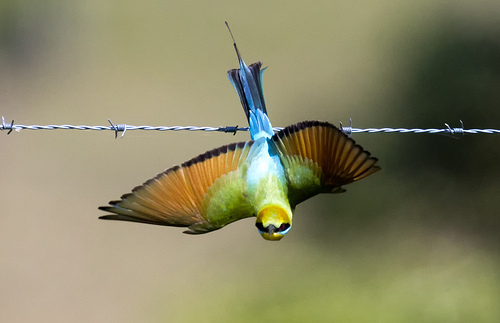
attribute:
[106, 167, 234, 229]
feathers — orange, black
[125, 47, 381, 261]
bird — blue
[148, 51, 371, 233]
bird — orange 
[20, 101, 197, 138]
fence — black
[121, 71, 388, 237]
bird — purple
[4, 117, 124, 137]
barbs — wire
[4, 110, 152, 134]
barbs — silver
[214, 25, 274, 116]
feathers — blue, short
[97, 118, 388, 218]
wings — orange 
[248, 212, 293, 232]
band — dark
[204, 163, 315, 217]
feathers — green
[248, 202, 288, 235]
semi-circle — orange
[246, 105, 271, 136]
feathers — pointed, blue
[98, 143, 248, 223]
feathers — connected, fan-looking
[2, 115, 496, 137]
wire — blue, twisted, taut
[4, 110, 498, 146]
barbed wire — silver, fencing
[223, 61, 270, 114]
tail feathers — blue, black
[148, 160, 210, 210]
feathers — orange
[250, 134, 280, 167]
feathers — blue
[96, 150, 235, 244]
wing — extended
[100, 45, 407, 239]
bird — yellow, green, multi-colored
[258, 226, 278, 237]
beak — brown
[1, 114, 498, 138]
barbed wire — silver, metal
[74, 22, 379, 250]
bird — flying, multi-colored